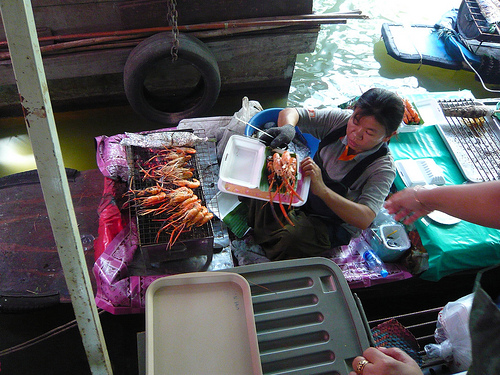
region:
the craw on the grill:
[123, 140, 213, 246]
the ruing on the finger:
[350, 355, 367, 373]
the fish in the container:
[215, 131, 311, 216]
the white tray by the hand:
[144, 273, 266, 373]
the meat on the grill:
[437, 96, 498, 125]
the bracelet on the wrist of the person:
[406, 180, 441, 219]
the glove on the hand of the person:
[253, 118, 302, 148]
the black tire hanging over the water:
[124, 31, 224, 124]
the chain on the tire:
[159, 1, 186, 60]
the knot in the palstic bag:
[422, 329, 457, 362]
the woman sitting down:
[240, 88, 403, 258]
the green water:
[1, 0, 498, 174]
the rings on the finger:
[354, 359, 367, 374]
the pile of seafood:
[122, 145, 212, 252]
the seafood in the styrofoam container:
[265, 150, 302, 231]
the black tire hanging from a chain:
[120, 30, 219, 125]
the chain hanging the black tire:
[163, 0, 179, 67]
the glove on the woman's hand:
[259, 124, 295, 148]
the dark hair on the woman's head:
[350, 85, 405, 147]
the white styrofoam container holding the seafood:
[217, 133, 303, 193]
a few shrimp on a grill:
[131, 138, 217, 249]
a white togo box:
[396, 153, 449, 188]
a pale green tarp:
[381, 91, 488, 278]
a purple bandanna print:
[88, 260, 144, 322]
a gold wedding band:
[350, 358, 369, 371]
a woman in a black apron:
[238, 85, 415, 257]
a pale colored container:
[370, 211, 412, 265]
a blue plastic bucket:
[243, 103, 325, 163]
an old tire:
[119, 25, 226, 132]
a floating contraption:
[378, 5, 495, 90]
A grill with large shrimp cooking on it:
[116, 136, 220, 242]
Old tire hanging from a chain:
[113, 28, 231, 122]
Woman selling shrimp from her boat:
[235, 73, 411, 275]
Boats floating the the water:
[0, 0, 499, 122]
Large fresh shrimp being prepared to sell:
[110, 135, 222, 250]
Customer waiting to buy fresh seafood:
[348, 179, 497, 372]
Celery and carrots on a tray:
[367, 84, 437, 136]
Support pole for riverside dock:
[3, 0, 53, 367]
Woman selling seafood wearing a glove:
[241, 73, 412, 287]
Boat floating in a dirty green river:
[2, 98, 486, 333]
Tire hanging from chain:
[120, 0, 225, 130]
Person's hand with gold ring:
[342, 342, 426, 374]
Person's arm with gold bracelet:
[380, 178, 498, 228]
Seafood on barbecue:
[117, 138, 215, 268]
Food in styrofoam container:
[217, 130, 314, 213]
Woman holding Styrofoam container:
[210, 77, 408, 281]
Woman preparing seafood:
[102, 81, 406, 302]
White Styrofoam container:
[390, 150, 452, 198]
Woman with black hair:
[239, 79, 407, 260]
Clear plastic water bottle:
[347, 233, 392, 283]